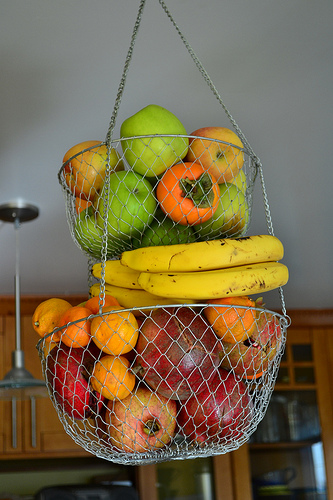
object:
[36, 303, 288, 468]
wire basket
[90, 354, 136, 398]
fruit